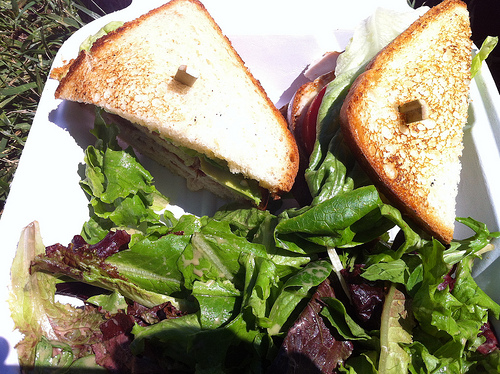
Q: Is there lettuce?
A: Yes, there is lettuce.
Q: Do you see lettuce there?
A: Yes, there is lettuce.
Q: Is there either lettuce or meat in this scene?
A: Yes, there is lettuce.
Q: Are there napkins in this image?
A: No, there are no napkins.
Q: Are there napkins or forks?
A: No, there are no napkins or forks.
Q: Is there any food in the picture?
A: Yes, there is food.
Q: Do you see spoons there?
A: No, there are no spoons.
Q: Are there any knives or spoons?
A: No, there are no spoons or knives.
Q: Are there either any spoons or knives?
A: No, there are no spoons or knives.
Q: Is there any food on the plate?
A: Yes, there is food on the plate.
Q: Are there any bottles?
A: No, there are no bottles.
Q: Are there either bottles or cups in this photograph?
A: No, there are no bottles or cups.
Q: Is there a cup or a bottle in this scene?
A: No, there are no bottles or cups.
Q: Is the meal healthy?
A: Yes, the meal is healthy.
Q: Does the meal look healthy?
A: Yes, the meal is healthy.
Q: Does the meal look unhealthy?
A: No, the meal is healthy.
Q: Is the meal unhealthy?
A: No, the meal is healthy.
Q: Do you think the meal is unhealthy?
A: No, the meal is healthy.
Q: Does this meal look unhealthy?
A: No, the meal is healthy.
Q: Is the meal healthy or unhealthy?
A: The meal is healthy.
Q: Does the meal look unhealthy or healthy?
A: The meal is healthy.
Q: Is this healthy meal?
A: Yes, this is healthy meal.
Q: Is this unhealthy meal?
A: No, this is healthy meal.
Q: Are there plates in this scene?
A: Yes, there is a plate.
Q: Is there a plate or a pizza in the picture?
A: Yes, there is a plate.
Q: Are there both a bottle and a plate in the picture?
A: No, there is a plate but no bottles.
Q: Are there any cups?
A: No, there are no cups.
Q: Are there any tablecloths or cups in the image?
A: No, there are no cups or tablecloths.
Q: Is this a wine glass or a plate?
A: This is a plate.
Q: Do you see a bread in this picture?
A: Yes, there is a bread.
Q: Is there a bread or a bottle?
A: Yes, there is a bread.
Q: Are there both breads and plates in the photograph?
A: Yes, there are both a bread and a plate.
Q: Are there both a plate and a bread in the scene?
A: Yes, there are both a bread and a plate.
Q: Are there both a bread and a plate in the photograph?
A: Yes, there are both a bread and a plate.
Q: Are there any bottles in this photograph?
A: No, there are no bottles.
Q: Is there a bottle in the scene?
A: No, there are no bottles.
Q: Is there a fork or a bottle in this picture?
A: No, there are no bottles or forks.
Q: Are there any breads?
A: Yes, there is a bread.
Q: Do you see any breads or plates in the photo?
A: Yes, there is a bread.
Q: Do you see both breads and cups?
A: No, there is a bread but no cups.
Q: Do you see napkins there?
A: No, there are no napkins.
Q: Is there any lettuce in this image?
A: Yes, there is lettuce.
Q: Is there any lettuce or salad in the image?
A: Yes, there is lettuce.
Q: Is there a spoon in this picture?
A: No, there are no spoons.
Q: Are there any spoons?
A: No, there are no spoons.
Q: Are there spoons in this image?
A: No, there are no spoons.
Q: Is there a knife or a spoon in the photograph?
A: No, there are no spoons or knives.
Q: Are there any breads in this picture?
A: Yes, there is a bread.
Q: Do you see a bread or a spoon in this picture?
A: Yes, there is a bread.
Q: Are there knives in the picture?
A: No, there are no knives.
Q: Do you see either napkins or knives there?
A: No, there are no knives or napkins.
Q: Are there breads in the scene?
A: Yes, there is a bread.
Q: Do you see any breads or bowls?
A: Yes, there is a bread.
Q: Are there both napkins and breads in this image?
A: No, there is a bread but no napkins.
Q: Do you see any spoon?
A: No, there are no spoons.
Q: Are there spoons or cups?
A: No, there are no spoons or cups.